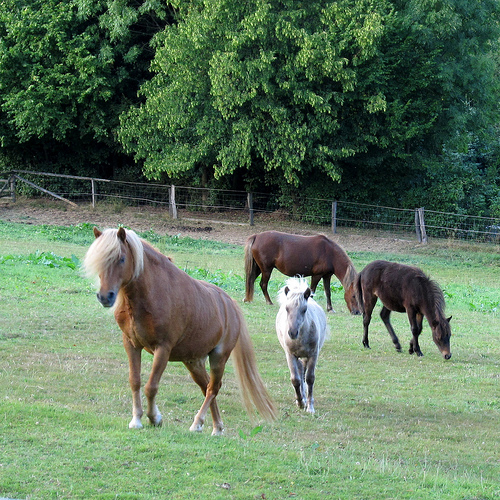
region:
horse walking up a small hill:
[70, 218, 277, 434]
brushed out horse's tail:
[226, 293, 281, 433]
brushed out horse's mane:
[76, 226, 148, 283]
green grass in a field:
[40, 414, 141, 474]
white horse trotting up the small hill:
[239, 276, 336, 433]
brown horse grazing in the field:
[365, 251, 461, 380]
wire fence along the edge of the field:
[34, 165, 169, 225]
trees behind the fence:
[419, 179, 479, 223]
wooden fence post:
[164, 172, 185, 222]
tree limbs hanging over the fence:
[144, 96, 255, 198]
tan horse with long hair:
[78, 227, 282, 437]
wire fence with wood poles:
[1, 169, 498, 249]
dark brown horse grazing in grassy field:
[351, 258, 453, 360]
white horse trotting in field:
[271, 274, 330, 419]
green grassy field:
[0, 220, 499, 497]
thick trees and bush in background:
[1, 0, 498, 242]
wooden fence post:
[331, 199, 337, 232]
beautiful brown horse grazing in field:
[241, 231, 361, 314]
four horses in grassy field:
[78, 226, 454, 438]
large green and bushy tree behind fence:
[118, 0, 385, 185]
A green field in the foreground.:
[1, 219, 497, 496]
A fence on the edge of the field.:
[1, 171, 499, 246]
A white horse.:
[274, 275, 326, 415]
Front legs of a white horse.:
[286, 345, 316, 411]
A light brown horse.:
[78, 225, 276, 433]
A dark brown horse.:
[356, 260, 451, 359]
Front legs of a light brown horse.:
[124, 335, 168, 427]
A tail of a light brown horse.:
[234, 297, 278, 426]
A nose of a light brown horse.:
[93, 287, 115, 307]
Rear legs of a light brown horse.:
[185, 352, 224, 435]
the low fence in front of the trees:
[2, 169, 498, 250]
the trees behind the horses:
[0, 0, 498, 240]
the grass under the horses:
[1, 216, 498, 499]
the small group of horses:
[77, 224, 451, 436]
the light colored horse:
[274, 272, 326, 414]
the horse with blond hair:
[78, 227, 281, 439]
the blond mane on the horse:
[80, 225, 142, 281]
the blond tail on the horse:
[231, 297, 277, 424]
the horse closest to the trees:
[242, 231, 360, 314]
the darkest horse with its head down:
[352, 259, 452, 359]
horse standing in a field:
[76, 210, 286, 451]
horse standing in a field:
[270, 275, 342, 418]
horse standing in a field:
[349, 261, 469, 357]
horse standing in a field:
[230, 225, 380, 321]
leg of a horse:
[117, 338, 151, 433]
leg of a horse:
[142, 334, 183, 430]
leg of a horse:
[180, 332, 234, 441]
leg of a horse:
[282, 343, 310, 416]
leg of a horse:
[358, 288, 377, 355]